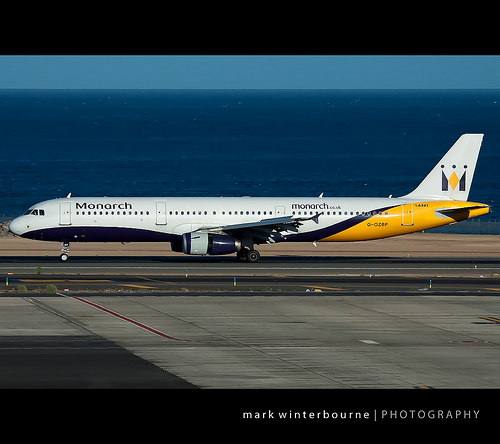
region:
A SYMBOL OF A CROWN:
[437, 158, 472, 195]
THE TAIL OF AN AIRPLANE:
[408, 123, 487, 205]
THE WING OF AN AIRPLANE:
[198, 210, 331, 235]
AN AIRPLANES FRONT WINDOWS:
[23, 201, 49, 221]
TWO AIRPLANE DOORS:
[55, 198, 175, 228]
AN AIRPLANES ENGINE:
[177, 230, 247, 256]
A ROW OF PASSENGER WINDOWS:
[74, 205, 399, 219]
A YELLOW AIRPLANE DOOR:
[397, 196, 419, 231]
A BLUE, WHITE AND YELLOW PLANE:
[7, 128, 494, 268]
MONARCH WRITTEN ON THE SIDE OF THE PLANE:
[73, 200, 136, 214]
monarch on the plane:
[288, 203, 330, 212]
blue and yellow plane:
[0, 127, 499, 264]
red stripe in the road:
[65, 292, 201, 349]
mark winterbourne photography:
[238, 398, 490, 425]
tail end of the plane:
[413, 127, 488, 201]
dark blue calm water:
[59, 98, 216, 145]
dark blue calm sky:
[117, 62, 174, 80]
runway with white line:
[90, 259, 327, 276]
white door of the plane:
[52, 199, 74, 231]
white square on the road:
[352, 325, 387, 356]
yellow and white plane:
[48, 140, 487, 237]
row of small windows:
[35, 207, 339, 222]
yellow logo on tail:
[415, 142, 473, 201]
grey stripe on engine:
[182, 225, 252, 268]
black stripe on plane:
[56, 190, 225, 251]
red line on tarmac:
[60, 290, 204, 348]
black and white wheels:
[42, 229, 91, 276]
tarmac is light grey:
[72, 311, 369, 388]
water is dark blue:
[124, 105, 283, 201]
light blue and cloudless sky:
[177, 54, 319, 82]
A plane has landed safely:
[5, 103, 497, 374]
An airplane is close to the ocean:
[0, 62, 496, 387]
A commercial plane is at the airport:
[0, 125, 496, 323]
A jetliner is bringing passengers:
[5, 111, 496, 342]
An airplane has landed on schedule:
[1, 105, 496, 338]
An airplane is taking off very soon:
[1, 107, 496, 345]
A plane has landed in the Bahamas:
[0, 115, 497, 340]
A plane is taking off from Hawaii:
[0, 113, 497, 324]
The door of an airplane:
[58, 200, 68, 221]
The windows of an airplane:
[171, 208, 261, 216]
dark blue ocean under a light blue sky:
[54, 59, 419, 172]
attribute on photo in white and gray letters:
[239, 402, 486, 427]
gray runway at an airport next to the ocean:
[27, 294, 492, 385]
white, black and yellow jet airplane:
[7, 129, 490, 265]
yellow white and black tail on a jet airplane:
[397, 129, 492, 244]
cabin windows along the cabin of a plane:
[74, 207, 391, 219]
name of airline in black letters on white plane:
[74, 196, 142, 214]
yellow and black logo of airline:
[434, 157, 469, 197]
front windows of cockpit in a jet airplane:
[23, 204, 50, 221]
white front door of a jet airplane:
[56, 197, 74, 230]